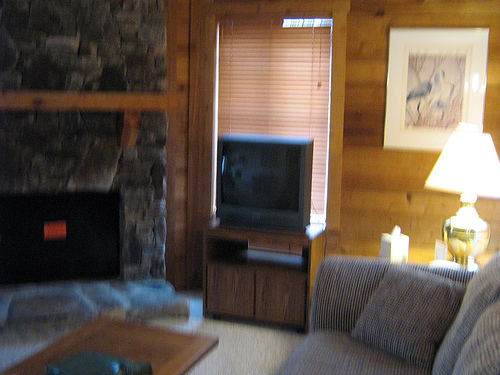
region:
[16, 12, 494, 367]
The picture is blurry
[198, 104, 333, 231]
TV on a stand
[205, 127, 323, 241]
The tv is analog.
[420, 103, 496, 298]
The lamp is turned on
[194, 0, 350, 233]
There's daylight outside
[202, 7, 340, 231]
The blinds are drawn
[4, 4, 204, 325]
Stone fireplace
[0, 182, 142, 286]
A fire is not burning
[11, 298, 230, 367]
Wooden coffee table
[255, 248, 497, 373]
Nobody on the couch on the right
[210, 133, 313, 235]
television sitting on small stand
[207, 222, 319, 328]
television stand made of wood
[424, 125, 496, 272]
table lamp with gold base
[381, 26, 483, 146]
picture hanging on wall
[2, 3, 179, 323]
stone fireplace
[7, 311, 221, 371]
coffee table in front of sofa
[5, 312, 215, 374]
coffee table made of wood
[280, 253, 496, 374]
grey sofa in living room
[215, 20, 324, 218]
blinds covering window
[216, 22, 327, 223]
window blinds are closed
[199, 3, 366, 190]
BROWN WOODEN BLINDS ON THE WINDOW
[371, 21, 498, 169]
Picture frame on the wall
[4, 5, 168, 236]
Stone mantel over fireplace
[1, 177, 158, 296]
Fireplace opposite to sofa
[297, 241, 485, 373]
Upholstered sofa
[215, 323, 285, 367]
Beige carpet in the room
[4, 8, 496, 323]
Living room in the house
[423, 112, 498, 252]
Table lamp with beige shade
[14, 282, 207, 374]
Coffee table in the middle of the room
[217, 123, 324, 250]
Television in the room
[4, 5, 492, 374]
slightly blurry image of a living room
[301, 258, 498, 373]
a grey striped couch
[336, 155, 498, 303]
side table between couch and wall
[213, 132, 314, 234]
a large television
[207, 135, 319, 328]
television sitting on tv stand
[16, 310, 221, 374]
brown wooden coffee table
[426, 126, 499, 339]
table lamp next to couch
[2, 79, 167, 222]
wooden shelf above fireplace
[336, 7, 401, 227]
wood panelling covering wall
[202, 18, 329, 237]
brown blinds on window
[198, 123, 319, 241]
dark grey television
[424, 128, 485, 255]
white lamp on table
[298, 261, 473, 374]
dark grey sofa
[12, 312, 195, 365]
dark brown table next to sofa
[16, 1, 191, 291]
stone and wood fireplace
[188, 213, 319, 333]
television on brown table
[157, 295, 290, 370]
carpet is off white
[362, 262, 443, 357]
dark grey pillow on sofa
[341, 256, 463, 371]
sofa pillow is square